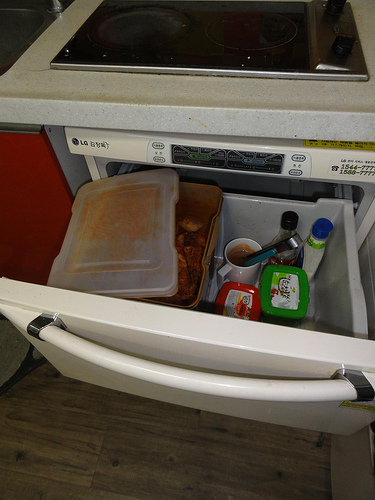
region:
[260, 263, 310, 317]
bright green and white plastic container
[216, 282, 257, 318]
red and white plastic top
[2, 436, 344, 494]
dark brown and black laminate floor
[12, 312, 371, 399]
silver and white dishwasher handle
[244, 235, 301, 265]
silver and blue cooking utensil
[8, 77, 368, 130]
white and grey counter top with red stain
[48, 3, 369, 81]
silver and black electric cooktop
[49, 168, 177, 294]
clear plastic top with red sauce stain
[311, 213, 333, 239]
bright blue bottle cap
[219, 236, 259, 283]
white ceramic coffee mug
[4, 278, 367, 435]
curved handle on white cabinet door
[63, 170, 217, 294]
white lid over brown container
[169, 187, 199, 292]
chunks of cooked meat in container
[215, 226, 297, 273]
white mug holding tongs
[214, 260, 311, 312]
small green and red containers with labels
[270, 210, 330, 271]
bottles with caps holding liquids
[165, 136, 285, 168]
dark panel with green and blue centers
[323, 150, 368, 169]
symbol of telephone followed by numbers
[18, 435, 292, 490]
wooden brown floor in front of cabinet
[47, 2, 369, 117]
metal panel set into counter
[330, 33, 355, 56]
black knob on stove top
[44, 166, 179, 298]
clear plastic lid with sauce on it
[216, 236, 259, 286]
white coffee mug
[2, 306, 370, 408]
white stove handle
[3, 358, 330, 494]
medium brown hard wood floor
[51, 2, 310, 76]
two burners of black stove top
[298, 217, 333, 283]
bottle of ranch dressing with a blue lid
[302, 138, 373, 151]
yellow sticker on top of white LG unit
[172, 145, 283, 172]
black display panel on LG unit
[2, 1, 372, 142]
white counter top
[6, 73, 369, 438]
A gross fridge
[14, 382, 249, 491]
dark brown wood floor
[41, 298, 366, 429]
white handle of a fridge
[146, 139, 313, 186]
a lot of different buttons and controls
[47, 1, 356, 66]
a black dirty stove top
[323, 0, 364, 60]
two knobs to the stove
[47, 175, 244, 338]
left over tomatoe sauce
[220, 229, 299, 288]
A dirty white cup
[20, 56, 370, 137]
a counter top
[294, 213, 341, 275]
an opened bottle of ranch dressing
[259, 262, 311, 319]
Green plastic top of a container.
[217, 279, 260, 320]
Red container top beside a green identical one.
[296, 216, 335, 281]
A white bottle of dressing with blue lid.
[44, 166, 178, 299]
A large plastic lid on a brown container.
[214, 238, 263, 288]
White mug with tongs inside it.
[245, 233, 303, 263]
Metal tongs sticking out of a white mug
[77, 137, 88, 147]
LG on the left side of a stove.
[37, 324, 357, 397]
Large long white handle between the silver.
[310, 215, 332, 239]
Blue lid on a salad dressing bottle.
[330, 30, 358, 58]
Bottom black knob of a stove.